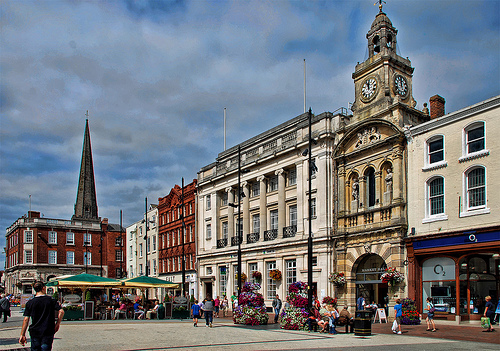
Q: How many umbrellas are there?
A: Two.